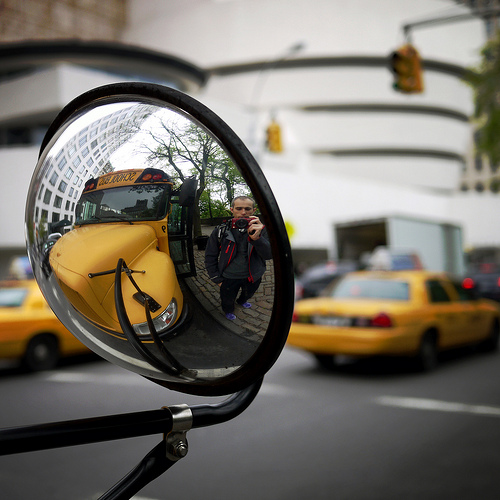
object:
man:
[207, 192, 278, 326]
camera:
[227, 218, 250, 239]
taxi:
[281, 264, 499, 375]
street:
[1, 324, 492, 496]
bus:
[44, 160, 200, 338]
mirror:
[22, 87, 291, 392]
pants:
[220, 277, 269, 314]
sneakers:
[224, 299, 259, 321]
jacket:
[207, 222, 273, 282]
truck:
[331, 214, 469, 283]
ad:
[377, 244, 427, 268]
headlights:
[129, 301, 183, 343]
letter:
[129, 167, 144, 186]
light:
[284, 38, 309, 55]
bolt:
[168, 436, 187, 459]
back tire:
[410, 332, 446, 370]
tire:
[27, 330, 64, 375]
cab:
[0, 273, 73, 369]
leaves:
[200, 175, 218, 217]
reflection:
[42, 134, 271, 368]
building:
[27, 40, 127, 247]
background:
[5, 11, 495, 392]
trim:
[222, 240, 236, 261]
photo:
[75, 146, 284, 339]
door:
[340, 216, 385, 270]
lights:
[259, 24, 446, 167]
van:
[306, 258, 363, 301]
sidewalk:
[192, 203, 277, 340]